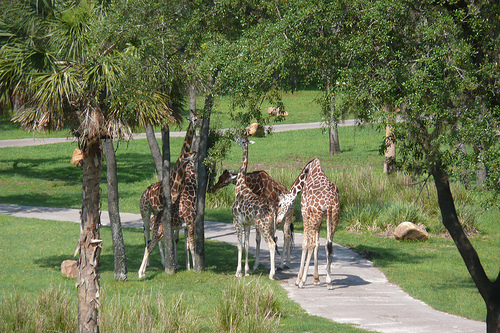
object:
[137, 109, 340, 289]
giraffes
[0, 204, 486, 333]
sidewalk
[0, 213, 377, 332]
grass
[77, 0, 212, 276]
tree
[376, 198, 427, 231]
bushes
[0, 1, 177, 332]
tree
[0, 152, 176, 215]
shadow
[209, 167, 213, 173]
leaves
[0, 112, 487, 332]
trail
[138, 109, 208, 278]
giraffe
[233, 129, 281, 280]
giraffe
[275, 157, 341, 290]
giraffe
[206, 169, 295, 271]
giraffe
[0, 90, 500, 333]
field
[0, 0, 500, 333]
park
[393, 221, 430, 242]
rock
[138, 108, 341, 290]
wildlife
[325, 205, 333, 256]
tail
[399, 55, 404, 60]
leaves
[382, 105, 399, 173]
trunk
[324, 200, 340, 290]
legs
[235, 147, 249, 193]
necks